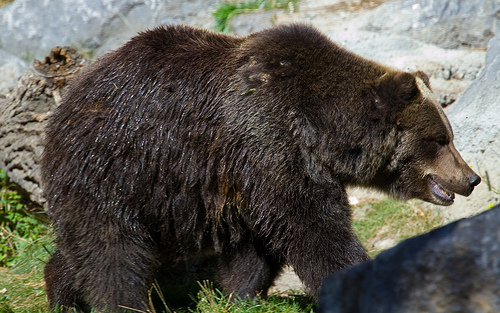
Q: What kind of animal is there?
A: Bear.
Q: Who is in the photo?
A: No people.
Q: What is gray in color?
A: The rocks.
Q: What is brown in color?
A: The fur.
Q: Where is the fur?
A: On the bear.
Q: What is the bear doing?
A: Walking.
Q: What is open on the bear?
A: The bear's mouth.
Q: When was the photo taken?
A: During the daytime.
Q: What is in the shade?
A: A rock.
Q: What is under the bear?
A: Grass.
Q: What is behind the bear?
A: Rock formation.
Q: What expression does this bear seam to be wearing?
A: A smile.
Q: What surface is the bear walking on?
A: Grass.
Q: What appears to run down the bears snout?
A: A white stripe.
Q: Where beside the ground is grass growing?
A: On the rocks.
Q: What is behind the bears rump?
A: A stump.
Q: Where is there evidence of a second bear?
A: Bottom right corner.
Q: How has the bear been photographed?
A: In profile.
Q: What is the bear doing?
A: Walking.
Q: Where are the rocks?
A: Behind the bear.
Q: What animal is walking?
A: The bear.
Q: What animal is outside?
A: The bear.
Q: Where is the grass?
A: Underneath the bear.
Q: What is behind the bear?
A: Rocks.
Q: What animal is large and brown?
A: The bear.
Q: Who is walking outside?
A: The bear.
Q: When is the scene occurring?
A: During the day.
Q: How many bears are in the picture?
A: 1.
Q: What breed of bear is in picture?
A: A brown bear.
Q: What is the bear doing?
A: Walking amongst the grass and rocks.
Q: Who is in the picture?
A: No one but the bear.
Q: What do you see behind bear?
A: Boulders.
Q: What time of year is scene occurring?
A: Summer.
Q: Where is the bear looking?
A: Left.